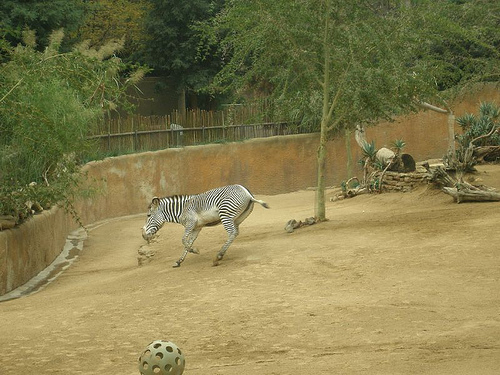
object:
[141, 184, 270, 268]
zebra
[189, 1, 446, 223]
tree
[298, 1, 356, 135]
branches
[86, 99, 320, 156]
fence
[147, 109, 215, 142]
sticks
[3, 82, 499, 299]
wall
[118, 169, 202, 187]
stone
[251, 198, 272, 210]
tail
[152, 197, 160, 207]
ear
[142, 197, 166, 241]
head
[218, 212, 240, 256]
leg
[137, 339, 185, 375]
ball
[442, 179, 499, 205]
log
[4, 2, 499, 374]
enclosure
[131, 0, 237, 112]
tree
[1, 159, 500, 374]
dirt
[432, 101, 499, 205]
tree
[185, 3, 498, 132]
leaves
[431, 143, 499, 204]
wood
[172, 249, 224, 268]
feet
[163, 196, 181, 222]
neck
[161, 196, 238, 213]
stripes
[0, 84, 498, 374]
pen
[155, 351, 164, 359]
holes